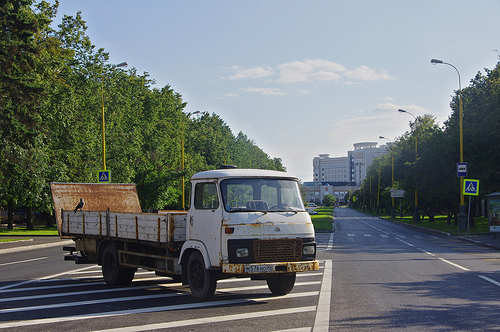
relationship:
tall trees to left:
[3, 54, 90, 172] [2, 99, 149, 279]